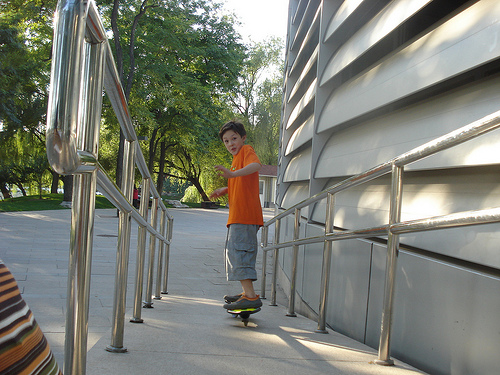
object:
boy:
[205, 103, 265, 328]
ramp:
[145, 315, 190, 370]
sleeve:
[0, 258, 65, 373]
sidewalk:
[80, 288, 431, 373]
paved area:
[30, 267, 407, 374]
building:
[269, 0, 499, 373]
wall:
[272, 210, 489, 364]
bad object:
[81, 123, 243, 195]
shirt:
[224, 145, 266, 225]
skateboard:
[224, 291, 264, 328]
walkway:
[84, 296, 426, 374]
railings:
[38, 15, 175, 372]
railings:
[261, 109, 498, 364]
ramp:
[91, 294, 426, 374]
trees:
[5, 0, 232, 187]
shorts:
[220, 220, 265, 283]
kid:
[209, 119, 266, 314]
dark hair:
[217, 119, 247, 140]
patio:
[0, 207, 290, 369]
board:
[226, 308, 261, 324]